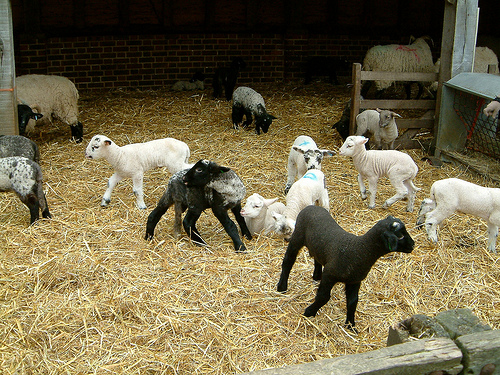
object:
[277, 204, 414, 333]
lamb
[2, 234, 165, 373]
hay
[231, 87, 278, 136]
lamb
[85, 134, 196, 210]
lamb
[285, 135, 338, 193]
lamb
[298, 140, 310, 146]
marking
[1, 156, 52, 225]
lamb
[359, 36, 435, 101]
sheep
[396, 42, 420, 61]
marking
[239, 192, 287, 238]
lamb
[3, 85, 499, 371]
pen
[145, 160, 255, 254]
sheep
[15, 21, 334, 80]
wall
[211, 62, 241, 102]
sheep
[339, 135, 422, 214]
sheep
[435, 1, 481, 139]
wood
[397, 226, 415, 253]
face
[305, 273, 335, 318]
leg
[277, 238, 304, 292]
leg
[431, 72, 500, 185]
table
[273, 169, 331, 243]
lamb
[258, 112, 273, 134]
head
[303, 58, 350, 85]
sheep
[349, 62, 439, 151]
fence